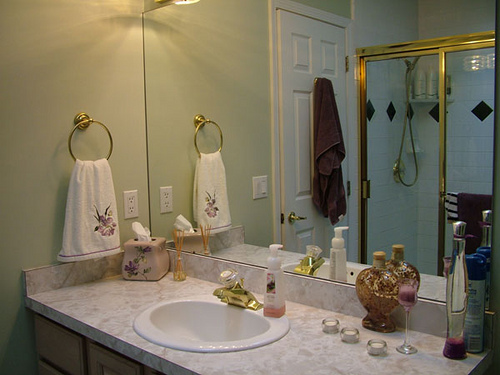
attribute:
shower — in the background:
[357, 38, 481, 262]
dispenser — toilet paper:
[120, 220, 170, 280]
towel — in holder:
[61, 108, 129, 265]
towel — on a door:
[311, 74, 349, 225]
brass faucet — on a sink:
[214, 267, 264, 312]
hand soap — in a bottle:
[265, 302, 287, 320]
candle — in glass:
[400, 284, 416, 304]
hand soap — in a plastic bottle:
[265, 301, 285, 315]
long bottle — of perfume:
[441, 219, 477, 359]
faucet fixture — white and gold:
[208, 267, 260, 314]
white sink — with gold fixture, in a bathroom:
[134, 292, 288, 352]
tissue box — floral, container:
[118, 232, 170, 281]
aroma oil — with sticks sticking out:
[168, 225, 189, 283]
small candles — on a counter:
[322, 315, 391, 357]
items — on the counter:
[120, 219, 466, 364]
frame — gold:
[348, 41, 388, 262]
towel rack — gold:
[64, 108, 115, 167]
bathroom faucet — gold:
[209, 265, 262, 313]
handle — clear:
[215, 266, 245, 289]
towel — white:
[56, 155, 125, 261]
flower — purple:
[91, 201, 118, 237]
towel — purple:
[308, 71, 354, 222]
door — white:
[262, 3, 365, 265]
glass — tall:
[393, 276, 424, 362]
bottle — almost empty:
[259, 239, 293, 324]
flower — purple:
[124, 253, 147, 282]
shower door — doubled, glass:
[348, 28, 498, 279]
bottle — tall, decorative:
[441, 215, 470, 361]